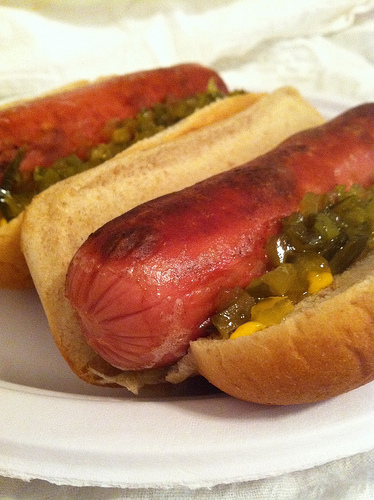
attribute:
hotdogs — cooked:
[57, 96, 372, 373]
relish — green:
[267, 184, 373, 263]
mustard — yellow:
[218, 320, 269, 353]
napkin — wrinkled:
[11, 2, 361, 118]